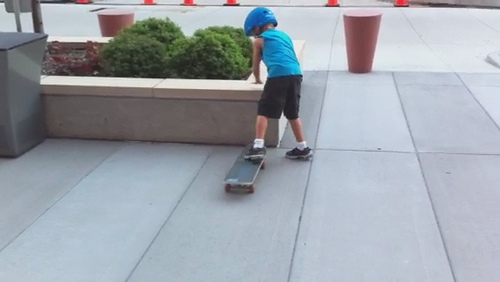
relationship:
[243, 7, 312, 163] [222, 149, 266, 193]
child on a skateboard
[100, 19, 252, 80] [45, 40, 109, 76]
bushes in a raise bed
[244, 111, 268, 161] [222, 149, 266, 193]
foot on skateboard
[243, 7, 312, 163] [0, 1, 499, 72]
child on a sidewalk